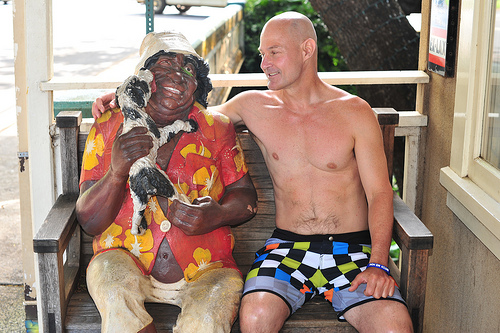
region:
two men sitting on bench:
[72, 17, 457, 330]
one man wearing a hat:
[47, 17, 267, 329]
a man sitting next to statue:
[98, 20, 396, 331]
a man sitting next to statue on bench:
[78, 24, 468, 328]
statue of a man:
[107, 5, 257, 297]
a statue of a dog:
[84, 76, 196, 243]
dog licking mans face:
[79, 18, 284, 284]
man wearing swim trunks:
[226, 13, 482, 330]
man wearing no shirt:
[219, 4, 446, 331]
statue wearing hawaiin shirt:
[50, 43, 215, 300]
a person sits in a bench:
[215, 13, 427, 329]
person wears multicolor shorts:
[206, 4, 422, 326]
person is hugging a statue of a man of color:
[78, 5, 407, 332]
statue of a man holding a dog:
[63, 30, 268, 332]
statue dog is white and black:
[93, 54, 210, 248]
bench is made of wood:
[16, 98, 441, 331]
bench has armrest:
[13, 97, 439, 332]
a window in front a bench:
[435, 2, 499, 272]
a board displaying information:
[413, 0, 464, 80]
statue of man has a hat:
[67, 15, 264, 331]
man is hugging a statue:
[80, 7, 407, 198]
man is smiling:
[216, 3, 390, 168]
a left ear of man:
[296, 31, 322, 69]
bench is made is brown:
[21, 100, 446, 327]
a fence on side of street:
[193, 3, 251, 79]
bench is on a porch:
[1, 11, 436, 331]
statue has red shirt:
[69, 23, 263, 331]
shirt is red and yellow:
[73, 96, 254, 281]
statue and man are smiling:
[96, 2, 366, 151]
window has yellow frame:
[434, 2, 498, 267]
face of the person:
[238, 7, 355, 118]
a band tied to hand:
[357, 254, 404, 284]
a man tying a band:
[346, 225, 391, 295]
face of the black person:
[115, 29, 224, 126]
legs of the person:
[246, 292, 451, 329]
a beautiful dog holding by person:
[118, 65, 200, 255]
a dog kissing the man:
[99, 54, 211, 256]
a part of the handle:
[398, 205, 445, 262]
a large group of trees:
[283, 2, 492, 127]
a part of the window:
[461, 27, 498, 213]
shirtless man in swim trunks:
[223, 14, 381, 330]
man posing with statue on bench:
[74, 7, 423, 329]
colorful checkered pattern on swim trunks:
[263, 247, 293, 299]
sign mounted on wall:
[423, 3, 456, 85]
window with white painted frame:
[451, 4, 498, 242]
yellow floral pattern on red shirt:
[180, 142, 225, 192]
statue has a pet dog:
[107, 70, 204, 243]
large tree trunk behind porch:
[309, 0, 438, 147]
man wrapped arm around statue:
[76, 23, 267, 153]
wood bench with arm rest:
[28, 107, 80, 331]